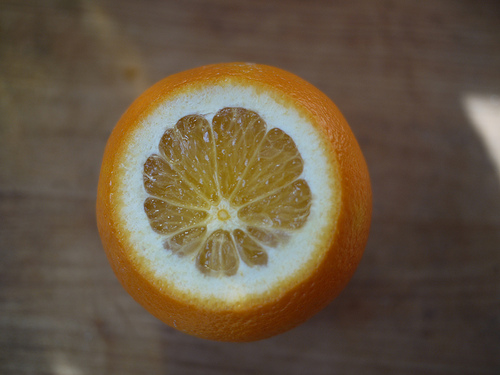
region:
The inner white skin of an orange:
[201, 95, 240, 103]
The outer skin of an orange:
[292, 85, 309, 96]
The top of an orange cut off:
[148, 118, 305, 273]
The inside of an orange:
[221, 121, 243, 169]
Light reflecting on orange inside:
[176, 137, 191, 150]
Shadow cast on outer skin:
[281, 309, 296, 322]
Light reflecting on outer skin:
[311, 99, 328, 112]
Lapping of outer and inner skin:
[114, 158, 121, 185]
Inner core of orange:
[212, 207, 232, 223]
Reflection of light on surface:
[482, 105, 496, 135]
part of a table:
[417, 206, 438, 242]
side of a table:
[391, 322, 395, 342]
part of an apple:
[310, 258, 324, 280]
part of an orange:
[271, 270, 283, 293]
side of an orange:
[216, 250, 225, 262]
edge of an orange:
[151, 273, 162, 285]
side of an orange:
[234, 222, 254, 255]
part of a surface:
[378, 303, 388, 311]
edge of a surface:
[385, 305, 403, 342]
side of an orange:
[323, 233, 335, 260]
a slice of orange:
[79, 54, 377, 371]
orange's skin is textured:
[325, 135, 391, 242]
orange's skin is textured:
[274, 63, 321, 128]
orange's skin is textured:
[149, 295, 254, 354]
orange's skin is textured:
[76, 175, 182, 325]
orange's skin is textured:
[299, 230, 393, 344]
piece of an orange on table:
[55, 59, 375, 346]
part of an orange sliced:
[83, 80, 343, 309]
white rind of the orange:
[125, 85, 312, 277]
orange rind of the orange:
[94, 60, 371, 331]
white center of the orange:
[197, 197, 242, 244]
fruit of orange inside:
[157, 103, 227, 201]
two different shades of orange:
[94, 116, 141, 180]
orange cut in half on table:
[64, 48, 385, 340]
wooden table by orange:
[0, 51, 70, 216]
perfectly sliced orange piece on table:
[84, 63, 354, 316]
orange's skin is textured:
[184, 50, 271, 104]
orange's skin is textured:
[316, 182, 403, 331]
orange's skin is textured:
[87, 118, 179, 262]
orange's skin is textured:
[119, 222, 224, 372]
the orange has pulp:
[114, 101, 250, 241]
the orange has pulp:
[206, 189, 289, 258]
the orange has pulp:
[217, 123, 282, 204]